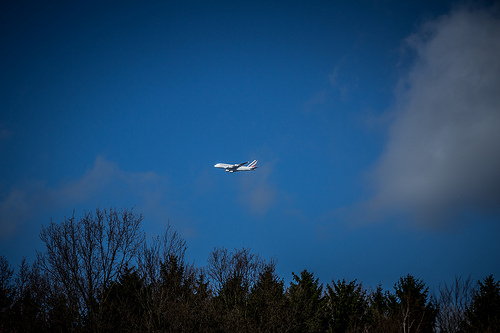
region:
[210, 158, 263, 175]
The plane is flying.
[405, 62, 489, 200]
The cloud is white.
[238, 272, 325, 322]
The trees are green.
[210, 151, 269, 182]
The plane is fast.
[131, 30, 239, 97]
Clear skies today.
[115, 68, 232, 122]
It is not raining.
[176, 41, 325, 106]
The plane is flying during the day.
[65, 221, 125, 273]
The tress has sticks.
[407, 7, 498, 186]
clouds in the sky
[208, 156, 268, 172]
white plane in air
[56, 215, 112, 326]
bare tree in woods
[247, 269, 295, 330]
tree with leaves in forest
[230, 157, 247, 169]
left wing on plane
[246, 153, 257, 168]
left tail wing on plane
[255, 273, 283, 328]
pine trees on land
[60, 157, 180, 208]
grey storm clouds in air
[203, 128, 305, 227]
a plane is in air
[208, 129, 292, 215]
plane is in motion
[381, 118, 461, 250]
sky is covereed of clouds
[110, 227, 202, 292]
plants are green incolor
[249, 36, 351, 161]
the sky is clear blue in color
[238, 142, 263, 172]
the plane has a red logo on tail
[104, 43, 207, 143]
this is the sky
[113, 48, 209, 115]
the sky is blue in color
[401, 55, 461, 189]
these are the clouds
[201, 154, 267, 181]
this is a jet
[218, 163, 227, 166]
the jet is white in color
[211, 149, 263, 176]
the jet is on air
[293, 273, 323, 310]
the leaves are green in color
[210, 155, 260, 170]
an airplane in the sky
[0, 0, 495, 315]
a clear blue sky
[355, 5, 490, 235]
a large cloud in the sky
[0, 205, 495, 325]
the tops of some trees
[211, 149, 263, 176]
a large white airplane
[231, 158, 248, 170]
the left wing of an airplane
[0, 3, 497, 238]
some clouds in the sky